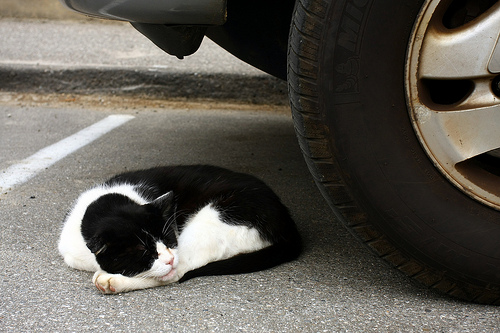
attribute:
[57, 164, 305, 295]
cat — black, sleeping, white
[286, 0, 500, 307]
tire — black, large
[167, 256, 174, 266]
nose — pink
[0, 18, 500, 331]
ground — gray, clean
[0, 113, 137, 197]
line — white